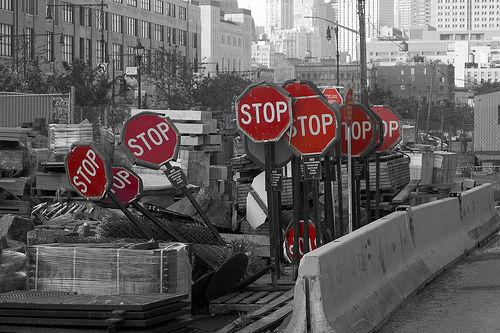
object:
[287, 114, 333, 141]
sign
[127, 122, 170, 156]
stop sign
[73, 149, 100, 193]
sign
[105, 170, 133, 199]
sign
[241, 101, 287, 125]
sign